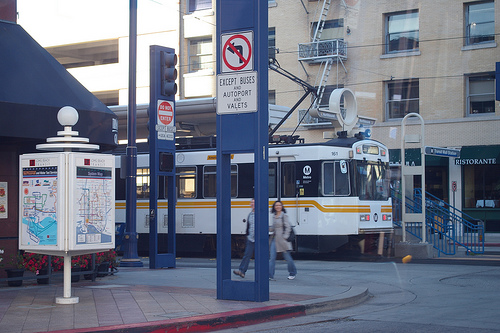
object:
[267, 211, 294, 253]
jacket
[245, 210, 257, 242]
shirt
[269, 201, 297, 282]
woman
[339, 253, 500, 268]
rails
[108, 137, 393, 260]
tram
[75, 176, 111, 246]
map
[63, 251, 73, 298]
pole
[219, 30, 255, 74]
sign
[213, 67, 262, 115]
sign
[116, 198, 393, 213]
stripe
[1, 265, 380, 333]
sidewalk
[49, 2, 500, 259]
building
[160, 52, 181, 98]
traffic light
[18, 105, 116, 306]
directory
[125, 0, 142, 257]
pole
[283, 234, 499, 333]
intersection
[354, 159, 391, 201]
windshield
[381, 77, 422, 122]
window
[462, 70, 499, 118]
window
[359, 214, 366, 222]
headlight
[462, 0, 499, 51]
window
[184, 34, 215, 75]
window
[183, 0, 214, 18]
window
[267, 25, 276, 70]
window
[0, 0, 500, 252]
background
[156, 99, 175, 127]
sign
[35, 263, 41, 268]
flowers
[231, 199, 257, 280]
man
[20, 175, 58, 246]
map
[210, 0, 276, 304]
frame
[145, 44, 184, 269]
frame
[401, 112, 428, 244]
bar